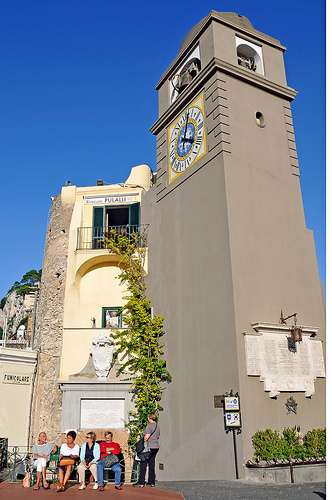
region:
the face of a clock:
[162, 91, 209, 185]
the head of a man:
[102, 428, 116, 443]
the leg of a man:
[110, 460, 122, 485]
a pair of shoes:
[96, 480, 125, 493]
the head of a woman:
[82, 430, 99, 443]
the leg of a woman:
[76, 458, 90, 485]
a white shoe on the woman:
[77, 479, 87, 491]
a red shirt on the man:
[96, 438, 123, 460]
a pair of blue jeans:
[94, 456, 124, 487]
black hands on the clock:
[177, 108, 196, 151]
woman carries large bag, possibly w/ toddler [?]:
[131, 409, 164, 489]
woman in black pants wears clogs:
[129, 479, 156, 490]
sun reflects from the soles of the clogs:
[131, 479, 156, 490]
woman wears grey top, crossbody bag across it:
[142, 421, 161, 449]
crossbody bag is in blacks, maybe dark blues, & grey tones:
[133, 437, 151, 464]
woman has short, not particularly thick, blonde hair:
[143, 408, 160, 425]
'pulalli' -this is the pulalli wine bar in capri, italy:
[101, 195, 127, 204]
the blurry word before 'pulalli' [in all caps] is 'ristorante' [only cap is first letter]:
[84, 196, 104, 205]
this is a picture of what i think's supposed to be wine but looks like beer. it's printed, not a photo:
[132, 194, 138, 201]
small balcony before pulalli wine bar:
[72, 220, 150, 251]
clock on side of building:
[156, 110, 209, 158]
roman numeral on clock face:
[195, 121, 204, 130]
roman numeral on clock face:
[194, 135, 205, 148]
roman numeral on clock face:
[194, 111, 202, 120]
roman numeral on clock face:
[182, 158, 192, 168]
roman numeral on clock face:
[175, 122, 184, 131]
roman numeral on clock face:
[174, 163, 182, 172]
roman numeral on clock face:
[173, 161, 180, 170]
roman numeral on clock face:
[167, 149, 174, 157]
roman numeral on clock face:
[165, 147, 176, 154]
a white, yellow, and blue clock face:
[166, 93, 207, 179]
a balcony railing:
[76, 217, 149, 253]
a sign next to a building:
[217, 387, 245, 483]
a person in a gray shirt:
[31, 431, 54, 492]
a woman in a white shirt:
[57, 429, 76, 490]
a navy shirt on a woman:
[85, 441, 96, 464]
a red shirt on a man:
[98, 439, 120, 464]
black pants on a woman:
[137, 444, 159, 481]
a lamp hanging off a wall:
[289, 315, 303, 344]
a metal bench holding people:
[15, 446, 140, 493]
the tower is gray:
[185, 348, 223, 376]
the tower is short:
[112, 19, 310, 325]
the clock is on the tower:
[157, 87, 222, 180]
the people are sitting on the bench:
[31, 429, 124, 493]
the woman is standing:
[134, 405, 161, 489]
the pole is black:
[222, 432, 246, 478]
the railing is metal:
[81, 223, 145, 241]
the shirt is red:
[101, 442, 119, 456]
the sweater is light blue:
[91, 444, 100, 462]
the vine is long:
[106, 239, 175, 418]